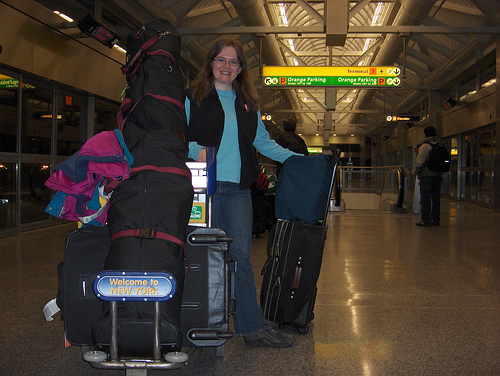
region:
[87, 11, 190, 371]
Long black bag on a trolley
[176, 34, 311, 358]
Lady with a grin on her face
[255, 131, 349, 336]
Travelling bag standing on the side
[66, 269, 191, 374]
Welcoming sign on the face of the trolley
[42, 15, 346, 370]
Lady standing with baggage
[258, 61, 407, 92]
Yellow and green sign with directions on it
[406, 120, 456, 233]
Man standing with a black backpack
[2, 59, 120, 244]
Row of framed grass windows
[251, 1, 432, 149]
Roof filled with bright lights lighting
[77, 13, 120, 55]
Display with red lights on it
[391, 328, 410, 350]
part of a floor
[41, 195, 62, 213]
part of the window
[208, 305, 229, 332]
back of a bag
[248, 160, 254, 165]
part of a jacket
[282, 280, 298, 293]
side of a bag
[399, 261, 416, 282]
part of the floor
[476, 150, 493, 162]
part of a door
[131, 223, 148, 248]
side of a bag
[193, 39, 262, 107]
the woman has long hair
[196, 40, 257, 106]
the woman's hair is light brown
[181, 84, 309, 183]
the woman is wearing a long sleeve shirt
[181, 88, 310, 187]
the shirt is blue in color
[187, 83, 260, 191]
the woman is wearing a vest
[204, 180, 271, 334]
the woman is wearing jeans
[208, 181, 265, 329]
the jeans are blue in color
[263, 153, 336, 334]
the woman is holding a luggage bag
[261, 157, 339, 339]
the bag is black in color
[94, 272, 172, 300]
a sign is low close to the floor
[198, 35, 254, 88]
a woman wearing glasses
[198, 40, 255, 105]
a woman with brown hair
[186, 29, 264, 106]
a woman with long hair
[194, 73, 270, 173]
a woman wearing a black vest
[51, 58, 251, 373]
several pieces of luggage on a cart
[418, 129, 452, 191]
a man with a black back pack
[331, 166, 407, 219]
the top of a escalator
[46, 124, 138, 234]
a pink and green coat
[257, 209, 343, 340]
a black suitcase with wheels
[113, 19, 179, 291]
a long bag with red straps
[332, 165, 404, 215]
an escalator in an airport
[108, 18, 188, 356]
a long black bag standing upward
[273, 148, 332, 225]
a blue bag on a suitcase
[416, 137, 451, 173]
man wearing a black backpack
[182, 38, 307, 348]
a woman standing next to her luggage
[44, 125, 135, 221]
a colorful coat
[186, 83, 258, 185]
woman wearing a black vest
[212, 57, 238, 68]
a woman wearing glasses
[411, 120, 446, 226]
a man standing next to the escalator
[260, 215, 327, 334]
a black suitcase with rolling wheel